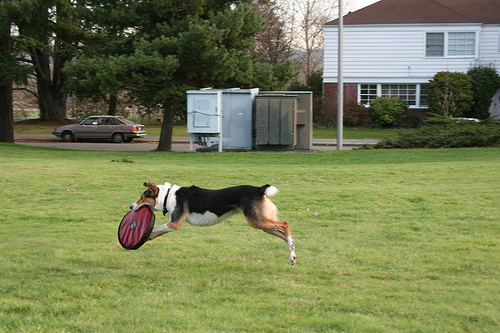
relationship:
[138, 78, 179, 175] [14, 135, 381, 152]
tree by street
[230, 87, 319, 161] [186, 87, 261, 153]
grey electric dumpster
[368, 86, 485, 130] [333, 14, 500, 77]
bushes by house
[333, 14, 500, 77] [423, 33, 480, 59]
house has windows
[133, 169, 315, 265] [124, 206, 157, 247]
dog has frisbee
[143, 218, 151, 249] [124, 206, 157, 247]
black around frisbee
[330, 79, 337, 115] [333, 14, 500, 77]
brick on house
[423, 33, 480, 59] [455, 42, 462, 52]
windows with glass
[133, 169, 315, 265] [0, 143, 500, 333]
dog in lawn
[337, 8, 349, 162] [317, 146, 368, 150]
pole in ground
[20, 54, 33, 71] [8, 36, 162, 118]
window on building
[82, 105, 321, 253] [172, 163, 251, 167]
jumping in air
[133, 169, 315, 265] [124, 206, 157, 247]
dog playing frisbee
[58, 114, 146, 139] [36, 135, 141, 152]
car on street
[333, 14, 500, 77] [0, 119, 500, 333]
house has two ground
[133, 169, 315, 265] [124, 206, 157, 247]
dog with frisbee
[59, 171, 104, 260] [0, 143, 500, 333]
ground has lawn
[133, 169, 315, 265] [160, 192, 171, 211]
dog has collar